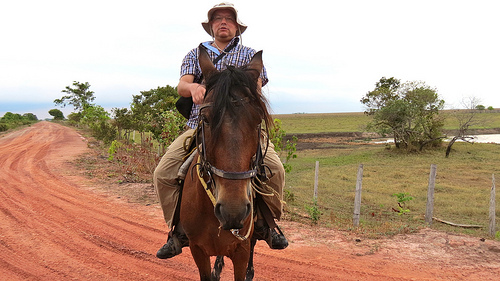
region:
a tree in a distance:
[361, 70, 436, 159]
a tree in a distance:
[436, 94, 482, 166]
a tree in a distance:
[476, 100, 486, 117]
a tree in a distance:
[485, 102, 499, 119]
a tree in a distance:
[111, 74, 178, 151]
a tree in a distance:
[272, 113, 325, 219]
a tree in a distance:
[86, 103, 113, 146]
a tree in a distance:
[57, 80, 100, 135]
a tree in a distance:
[48, 105, 65, 120]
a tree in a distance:
[21, 108, 41, 123]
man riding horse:
[141, 3, 304, 215]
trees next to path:
[345, 53, 475, 163]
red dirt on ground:
[35, 160, 121, 240]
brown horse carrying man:
[156, 76, 273, 240]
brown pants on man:
[128, 126, 197, 226]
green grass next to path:
[345, 158, 457, 199]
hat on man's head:
[188, 0, 261, 49]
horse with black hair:
[176, 63, 277, 187]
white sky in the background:
[80, 20, 152, 85]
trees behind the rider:
[66, 62, 162, 154]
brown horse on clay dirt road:
[155, 42, 293, 279]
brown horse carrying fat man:
[160, 42, 276, 279]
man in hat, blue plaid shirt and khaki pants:
[147, 2, 299, 259]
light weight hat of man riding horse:
[196, 0, 251, 42]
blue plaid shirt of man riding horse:
[167, 40, 269, 123]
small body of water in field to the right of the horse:
[366, 124, 498, 146]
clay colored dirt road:
[8, 127, 85, 278]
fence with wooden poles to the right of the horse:
[300, 152, 495, 235]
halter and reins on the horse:
[190, 92, 267, 242]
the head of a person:
[199, 0, 256, 42]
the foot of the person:
[251, 214, 294, 253]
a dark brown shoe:
[151, 226, 193, 266]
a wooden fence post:
[345, 154, 367, 234]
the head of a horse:
[181, 43, 284, 240]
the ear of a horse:
[193, 37, 218, 82]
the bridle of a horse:
[181, 111, 269, 187]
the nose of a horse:
[211, 196, 256, 228]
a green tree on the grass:
[361, 67, 448, 164]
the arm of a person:
[177, 50, 215, 111]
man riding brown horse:
[145, 8, 327, 275]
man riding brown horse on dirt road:
[71, 10, 408, 280]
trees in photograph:
[35, 55, 497, 186]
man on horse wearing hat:
[112, 0, 340, 157]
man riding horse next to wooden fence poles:
[80, 51, 492, 266]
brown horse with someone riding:
[158, 45, 330, 252]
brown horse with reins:
[160, 14, 331, 278]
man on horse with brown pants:
[118, 12, 393, 270]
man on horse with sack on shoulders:
[150, 17, 325, 198]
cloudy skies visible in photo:
[34, 61, 491, 278]